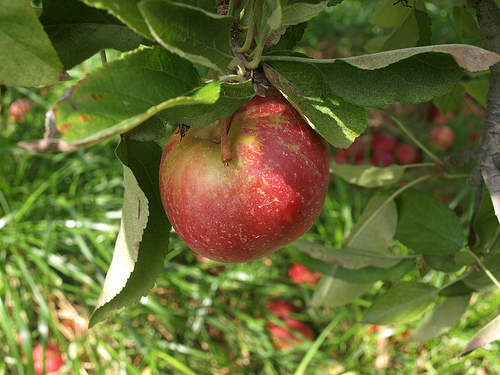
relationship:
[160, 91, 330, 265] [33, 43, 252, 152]
apple by leaf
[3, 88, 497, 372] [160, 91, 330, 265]
grass by apple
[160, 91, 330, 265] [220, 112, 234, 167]
apple has stem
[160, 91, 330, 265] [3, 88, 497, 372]
apple in grass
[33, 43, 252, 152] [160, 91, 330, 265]
leaf by apple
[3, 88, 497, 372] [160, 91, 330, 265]
grass below apple